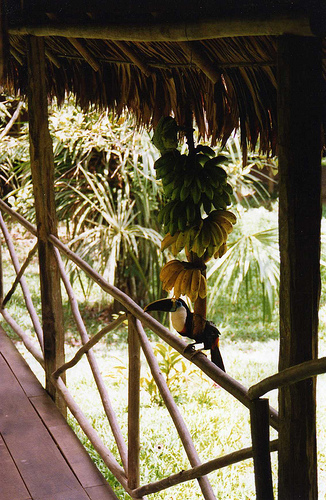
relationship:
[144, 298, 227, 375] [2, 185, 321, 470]
toucan on rail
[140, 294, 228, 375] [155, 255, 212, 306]
toucan under bananas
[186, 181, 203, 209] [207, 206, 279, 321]
banana on palm tree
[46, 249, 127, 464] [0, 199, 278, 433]
x in rail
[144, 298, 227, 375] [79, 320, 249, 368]
toucan on railing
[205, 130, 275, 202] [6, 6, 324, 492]
plant near tent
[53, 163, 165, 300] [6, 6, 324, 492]
plant near tent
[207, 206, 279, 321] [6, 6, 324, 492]
palm tree near tent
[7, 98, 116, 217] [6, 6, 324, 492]
plant near tent